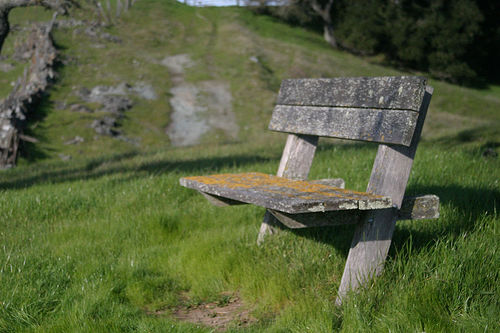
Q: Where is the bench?
A: In a park.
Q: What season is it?
A: Summer.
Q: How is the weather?
A: Sunny.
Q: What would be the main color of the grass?
A: Green.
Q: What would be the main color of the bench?
A: Grey.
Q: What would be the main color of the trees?
A: Green.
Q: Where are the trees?
A: In the back.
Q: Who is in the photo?
A: No people.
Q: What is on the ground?
A: Shadows.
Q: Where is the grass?
A: Under the bench.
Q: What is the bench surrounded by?
A: Green grass.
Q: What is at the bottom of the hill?
A: A rock wall.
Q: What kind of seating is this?
A: Bench.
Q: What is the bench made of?
A: Wood.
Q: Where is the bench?
A: Grass field.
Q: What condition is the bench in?
A: Disrepair.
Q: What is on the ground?
A: Grass.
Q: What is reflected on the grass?
A: Shadow of bench.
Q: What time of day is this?
A: Daylight hours.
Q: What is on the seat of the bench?
A: Brown debri.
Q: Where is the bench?
A: On a hill.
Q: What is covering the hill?
A: Grass.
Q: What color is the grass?
A: Green.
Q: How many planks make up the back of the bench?
A: Two.